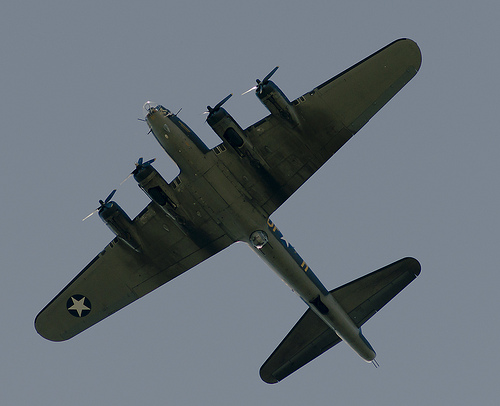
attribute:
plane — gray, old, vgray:
[33, 28, 455, 375]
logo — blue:
[56, 298, 100, 314]